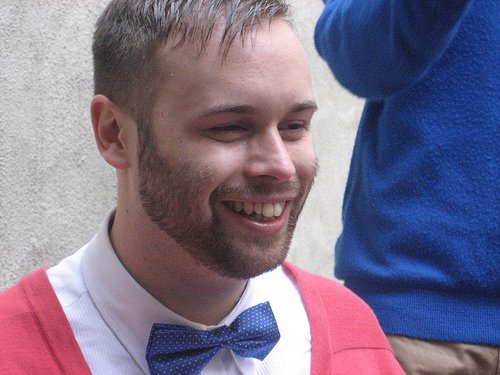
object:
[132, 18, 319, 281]
face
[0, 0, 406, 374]
man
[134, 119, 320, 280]
beard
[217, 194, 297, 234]
smile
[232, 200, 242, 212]
tooth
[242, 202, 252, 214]
tooth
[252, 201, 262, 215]
tooth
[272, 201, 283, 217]
tooth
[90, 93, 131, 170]
ear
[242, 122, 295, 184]
nose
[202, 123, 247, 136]
eye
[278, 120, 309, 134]
eye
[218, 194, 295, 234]
mouth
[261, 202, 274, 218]
teeth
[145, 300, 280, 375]
bow tie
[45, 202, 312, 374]
shirt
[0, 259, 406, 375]
sweater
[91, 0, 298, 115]
hair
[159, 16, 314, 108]
forehead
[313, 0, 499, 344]
sweater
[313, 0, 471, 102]
elbow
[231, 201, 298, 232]
lip